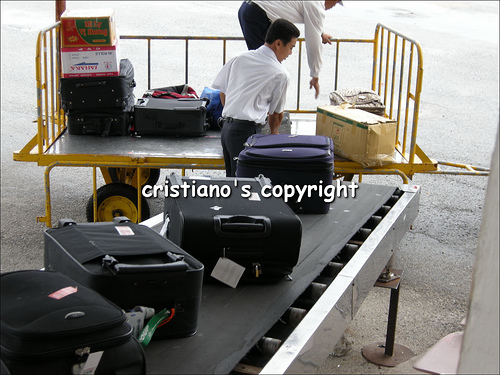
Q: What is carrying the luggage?
A: A conveyor belt.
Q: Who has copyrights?
A: Cristiano.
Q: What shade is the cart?
A: Yellow.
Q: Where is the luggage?
A: On the conveyor belt.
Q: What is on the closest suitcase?
A: A green tag.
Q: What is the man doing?
A: Moving luggage.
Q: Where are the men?
A: At the airport.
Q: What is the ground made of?
A: Cement.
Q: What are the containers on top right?
A: Boxes.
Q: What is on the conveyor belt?
A: Luggage.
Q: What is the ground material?
A: Pavement.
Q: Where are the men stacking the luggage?
A: On the luggage cart.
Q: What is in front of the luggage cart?
A: A conveyor belt.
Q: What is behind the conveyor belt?
A: A luggage cart.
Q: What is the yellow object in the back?
A: A luggage cart.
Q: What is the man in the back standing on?
A: A luggage cart.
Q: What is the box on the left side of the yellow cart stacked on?
A: Luggage.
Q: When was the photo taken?
A: Daytime.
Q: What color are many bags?
A: Black.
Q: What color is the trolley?
A: Yellow.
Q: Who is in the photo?
A: Two men.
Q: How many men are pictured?
A: Two.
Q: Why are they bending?
A: To load.